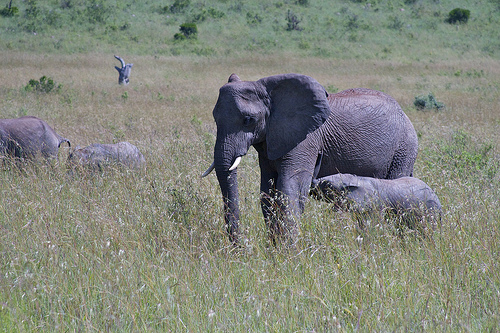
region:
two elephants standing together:
[208, 62, 451, 254]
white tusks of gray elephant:
[198, 159, 241, 184]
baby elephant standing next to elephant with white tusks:
[314, 169, 440, 244]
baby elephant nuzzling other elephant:
[306, 176, 444, 246]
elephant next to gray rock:
[4, 114, 66, 178]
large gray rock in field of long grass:
[64, 139, 146, 176]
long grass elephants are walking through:
[8, 54, 493, 329]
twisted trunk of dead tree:
[110, 52, 130, 85]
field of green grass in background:
[5, 4, 492, 43]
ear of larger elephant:
[268, 72, 323, 156]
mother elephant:
[198, 70, 418, 257]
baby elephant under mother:
[312, 178, 444, 244]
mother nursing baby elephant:
[205, 71, 440, 250]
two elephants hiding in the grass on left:
[1, 120, 146, 167]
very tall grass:
[6, 52, 498, 329]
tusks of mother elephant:
[203, 158, 240, 174]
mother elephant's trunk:
[213, 139, 247, 243]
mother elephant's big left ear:
[263, 77, 327, 158]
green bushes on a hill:
[0, 3, 496, 57]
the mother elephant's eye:
[240, 112, 255, 124]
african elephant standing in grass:
[218, 70, 425, 223]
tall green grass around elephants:
[84, 173, 384, 331]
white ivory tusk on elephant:
[226, 150, 256, 189]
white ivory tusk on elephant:
[206, 155, 225, 178]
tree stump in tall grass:
[104, 36, 149, 81]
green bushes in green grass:
[22, 58, 81, 98]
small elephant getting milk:
[316, 155, 473, 251]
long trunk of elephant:
[200, 129, 242, 283]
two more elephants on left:
[12, 112, 147, 185]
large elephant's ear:
[264, 61, 352, 166]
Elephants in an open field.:
[4, 67, 448, 251]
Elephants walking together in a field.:
[4, 69, 476, 244]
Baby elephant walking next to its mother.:
[314, 177, 444, 239]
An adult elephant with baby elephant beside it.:
[202, 74, 444, 244]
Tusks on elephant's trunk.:
[203, 151, 243, 176]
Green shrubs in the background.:
[4, 7, 483, 68]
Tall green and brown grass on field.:
[7, 94, 477, 323]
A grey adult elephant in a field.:
[199, 69, 421, 258]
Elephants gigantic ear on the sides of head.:
[217, 52, 332, 155]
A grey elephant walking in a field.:
[72, 137, 147, 174]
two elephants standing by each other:
[190, 66, 437, 248]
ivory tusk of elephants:
[231, 148, 248, 171]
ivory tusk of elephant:
[189, 156, 217, 183]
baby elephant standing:
[312, 177, 434, 234]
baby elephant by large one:
[289, 175, 437, 253]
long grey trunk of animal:
[214, 137, 249, 259]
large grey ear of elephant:
[267, 68, 329, 157]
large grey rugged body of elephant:
[235, 82, 432, 214]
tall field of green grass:
[37, 180, 187, 302]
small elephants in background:
[0, 99, 168, 217]